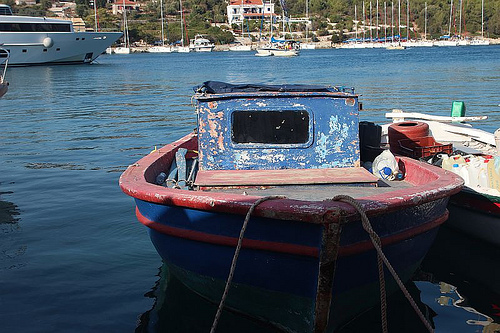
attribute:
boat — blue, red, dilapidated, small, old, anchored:
[119, 85, 465, 331]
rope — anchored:
[379, 243, 385, 332]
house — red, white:
[226, 1, 274, 38]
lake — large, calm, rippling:
[147, 53, 498, 82]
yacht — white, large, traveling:
[0, 4, 124, 66]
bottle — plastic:
[452, 163, 469, 186]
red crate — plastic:
[399, 136, 453, 156]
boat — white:
[189, 34, 214, 53]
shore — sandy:
[215, 42, 342, 49]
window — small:
[233, 112, 308, 144]